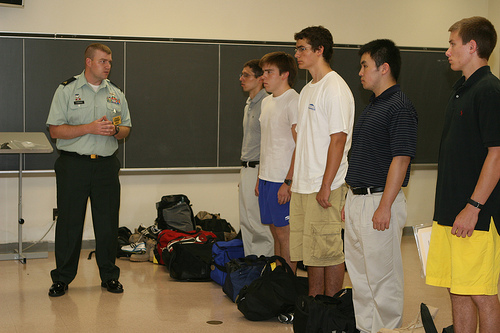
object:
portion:
[133, 45, 207, 118]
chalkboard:
[0, 33, 462, 175]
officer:
[45, 42, 132, 297]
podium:
[0, 132, 53, 265]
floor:
[0, 234, 500, 333]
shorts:
[424, 216, 500, 296]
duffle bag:
[168, 236, 218, 283]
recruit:
[421, 16, 500, 333]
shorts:
[289, 184, 347, 267]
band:
[467, 198, 484, 210]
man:
[286, 24, 355, 297]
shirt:
[239, 87, 270, 163]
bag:
[234, 254, 310, 321]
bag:
[208, 238, 244, 286]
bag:
[152, 227, 217, 265]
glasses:
[294, 45, 313, 53]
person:
[339, 37, 420, 333]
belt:
[350, 186, 384, 195]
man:
[235, 59, 277, 259]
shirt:
[288, 69, 354, 195]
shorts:
[257, 178, 290, 227]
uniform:
[45, 68, 132, 285]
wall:
[0, 0, 500, 237]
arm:
[466, 83, 499, 204]